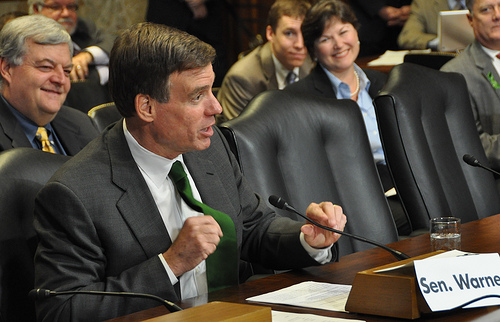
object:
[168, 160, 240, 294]
tie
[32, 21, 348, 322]
man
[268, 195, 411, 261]
microphone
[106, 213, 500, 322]
table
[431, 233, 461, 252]
water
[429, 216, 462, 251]
glass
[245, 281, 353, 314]
paper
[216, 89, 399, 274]
chair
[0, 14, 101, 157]
man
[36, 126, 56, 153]
tie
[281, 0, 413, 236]
women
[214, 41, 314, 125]
suit jacket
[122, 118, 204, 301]
shirt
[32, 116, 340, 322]
jacket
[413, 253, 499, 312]
name tag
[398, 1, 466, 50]
person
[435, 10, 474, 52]
laptop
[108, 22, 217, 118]
hair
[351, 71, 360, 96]
pearls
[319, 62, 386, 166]
shirt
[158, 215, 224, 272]
hand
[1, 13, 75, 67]
hair